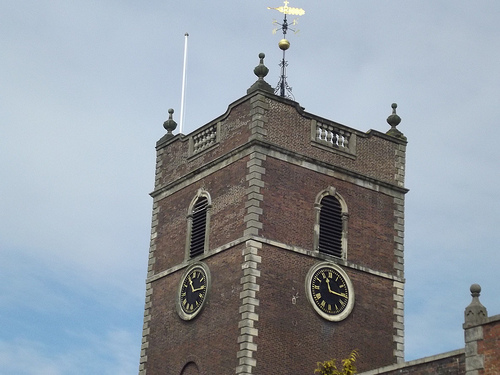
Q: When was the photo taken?
A: Daytime.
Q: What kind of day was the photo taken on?
A: Clear.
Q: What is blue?
A: Sky.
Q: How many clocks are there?
A: Two.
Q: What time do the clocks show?
A: 11:16.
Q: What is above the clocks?
A: Windows.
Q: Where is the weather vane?
A: Roof.